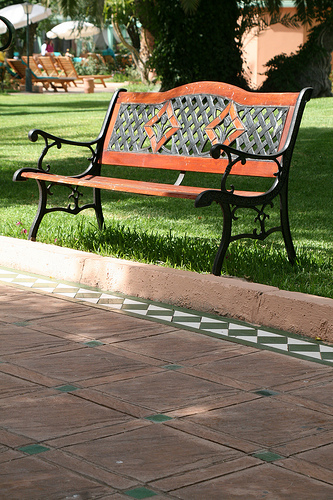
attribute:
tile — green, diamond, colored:
[170, 312, 205, 329]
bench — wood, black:
[13, 79, 316, 278]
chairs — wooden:
[8, 51, 114, 91]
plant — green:
[3, 69, 28, 90]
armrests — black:
[23, 132, 291, 185]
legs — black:
[30, 215, 293, 262]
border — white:
[6, 269, 325, 365]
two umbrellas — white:
[3, 3, 106, 56]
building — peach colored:
[233, 6, 303, 83]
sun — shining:
[108, 25, 121, 49]